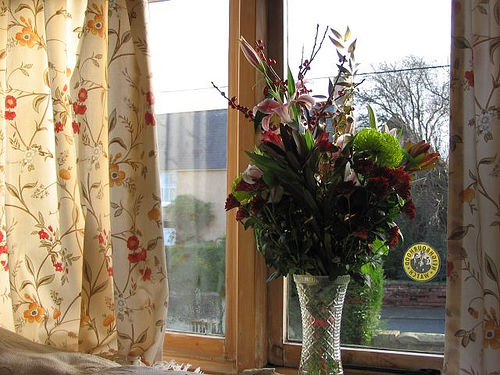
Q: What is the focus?
A: Flowers in glass vase in open window.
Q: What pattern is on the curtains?
A: Floral.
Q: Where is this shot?
A: Window.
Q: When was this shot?
A: Daytime.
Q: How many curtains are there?
A: 2.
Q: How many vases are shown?
A: 1.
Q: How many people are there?
A: 0.